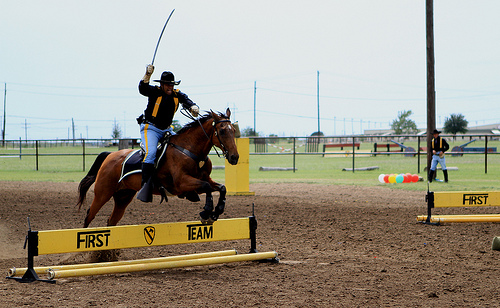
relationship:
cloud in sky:
[0, 0, 500, 142] [1, 0, 498, 119]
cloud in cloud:
[138, 2, 458, 137] [0, 0, 500, 142]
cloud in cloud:
[0, 0, 500, 142] [0, 0, 500, 142]